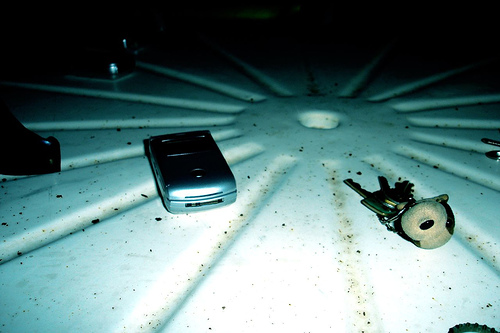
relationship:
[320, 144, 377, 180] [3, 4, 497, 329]
specks on table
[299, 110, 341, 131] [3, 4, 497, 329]
hole in middle of table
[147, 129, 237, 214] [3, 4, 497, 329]
cell phone on table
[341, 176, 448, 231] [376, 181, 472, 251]
key attached to key chain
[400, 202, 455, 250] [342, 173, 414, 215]
key chain holding keys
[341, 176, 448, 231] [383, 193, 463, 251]
key on keychain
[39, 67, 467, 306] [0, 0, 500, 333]
indentions on table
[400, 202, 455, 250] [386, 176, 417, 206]
key chain on key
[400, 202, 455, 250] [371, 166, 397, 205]
key chain on key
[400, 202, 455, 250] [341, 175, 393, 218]
key chain on key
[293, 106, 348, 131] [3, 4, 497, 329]
hole in table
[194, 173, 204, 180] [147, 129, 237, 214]
circle on cell phone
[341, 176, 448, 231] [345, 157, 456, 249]
key attached to keychain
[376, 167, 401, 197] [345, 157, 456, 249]
key attached to keychain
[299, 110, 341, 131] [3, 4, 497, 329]
hole in table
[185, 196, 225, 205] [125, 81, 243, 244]
charging port on phone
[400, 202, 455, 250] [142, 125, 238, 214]
key chain near phone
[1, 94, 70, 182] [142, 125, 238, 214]
black object near phone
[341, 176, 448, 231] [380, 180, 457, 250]
key on ring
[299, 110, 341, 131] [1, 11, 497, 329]
hole on surface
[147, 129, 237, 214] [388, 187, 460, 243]
cell phone next to keychain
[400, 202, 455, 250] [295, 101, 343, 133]
key chain around hole